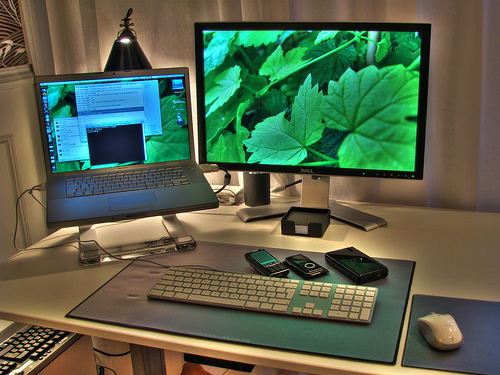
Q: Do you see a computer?
A: Yes, there is a computer.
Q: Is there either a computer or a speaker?
A: Yes, there is a computer.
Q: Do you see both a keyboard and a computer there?
A: Yes, there are both a computer and a keyboard.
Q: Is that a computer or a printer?
A: That is a computer.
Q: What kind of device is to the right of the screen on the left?
A: The device is a computer.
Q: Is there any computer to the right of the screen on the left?
A: Yes, there is a computer to the right of the screen.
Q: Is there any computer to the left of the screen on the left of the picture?
A: No, the computer is to the right of the screen.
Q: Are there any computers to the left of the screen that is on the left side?
A: No, the computer is to the right of the screen.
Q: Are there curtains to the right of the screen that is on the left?
A: No, there is a computer to the right of the screen.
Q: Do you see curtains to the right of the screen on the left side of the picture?
A: No, there is a computer to the right of the screen.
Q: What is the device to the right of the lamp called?
A: The device is a computer.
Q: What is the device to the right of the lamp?
A: The device is a computer.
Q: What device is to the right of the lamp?
A: The device is a computer.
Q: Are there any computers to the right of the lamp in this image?
A: Yes, there is a computer to the right of the lamp.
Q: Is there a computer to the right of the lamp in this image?
A: Yes, there is a computer to the right of the lamp.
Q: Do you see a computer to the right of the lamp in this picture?
A: Yes, there is a computer to the right of the lamp.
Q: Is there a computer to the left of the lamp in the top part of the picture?
A: No, the computer is to the right of the lamp.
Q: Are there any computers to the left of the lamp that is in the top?
A: No, the computer is to the right of the lamp.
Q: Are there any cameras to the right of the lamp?
A: No, there is a computer to the right of the lamp.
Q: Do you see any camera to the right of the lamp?
A: No, there is a computer to the right of the lamp.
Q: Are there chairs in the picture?
A: No, there are no chairs.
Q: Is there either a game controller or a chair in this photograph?
A: No, there are no chairs or game controllers.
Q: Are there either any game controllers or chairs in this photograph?
A: No, there are no chairs or game controllers.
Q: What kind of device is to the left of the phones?
A: The device is a screen.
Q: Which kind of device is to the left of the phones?
A: The device is a screen.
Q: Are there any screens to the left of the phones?
A: Yes, there is a screen to the left of the phones.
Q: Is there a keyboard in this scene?
A: Yes, there is a keyboard.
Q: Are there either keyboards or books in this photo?
A: Yes, there is a keyboard.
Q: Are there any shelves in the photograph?
A: No, there are no shelves.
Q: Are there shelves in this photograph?
A: No, there are no shelves.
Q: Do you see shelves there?
A: No, there are no shelves.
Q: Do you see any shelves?
A: No, there are no shelves.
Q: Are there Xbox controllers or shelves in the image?
A: No, there are no shelves or Xbox controllers.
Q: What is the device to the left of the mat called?
A: The device is a keyboard.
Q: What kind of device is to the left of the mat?
A: The device is a keyboard.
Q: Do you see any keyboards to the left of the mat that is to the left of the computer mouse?
A: Yes, there is a keyboard to the left of the mat.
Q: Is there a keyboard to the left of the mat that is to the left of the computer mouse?
A: Yes, there is a keyboard to the left of the mat.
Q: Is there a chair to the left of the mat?
A: No, there is a keyboard to the left of the mat.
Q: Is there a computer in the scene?
A: Yes, there is a computer.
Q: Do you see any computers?
A: Yes, there is a computer.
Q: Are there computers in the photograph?
A: Yes, there is a computer.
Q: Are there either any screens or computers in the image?
A: Yes, there is a computer.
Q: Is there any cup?
A: No, there are no cups.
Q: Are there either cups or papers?
A: No, there are no cups or papers.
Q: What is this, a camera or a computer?
A: This is a computer.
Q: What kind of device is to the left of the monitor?
A: The device is a computer.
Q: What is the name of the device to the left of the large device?
A: The device is a computer.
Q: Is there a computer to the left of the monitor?
A: Yes, there is a computer to the left of the monitor.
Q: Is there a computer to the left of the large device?
A: Yes, there is a computer to the left of the monitor.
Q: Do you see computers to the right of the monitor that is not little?
A: No, the computer is to the left of the monitor.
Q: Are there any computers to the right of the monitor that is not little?
A: No, the computer is to the left of the monitor.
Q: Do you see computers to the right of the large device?
A: No, the computer is to the left of the monitor.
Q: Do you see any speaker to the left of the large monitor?
A: No, there is a computer to the left of the monitor.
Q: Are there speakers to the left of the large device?
A: No, there is a computer to the left of the monitor.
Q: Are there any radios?
A: No, there are no radios.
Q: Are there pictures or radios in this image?
A: No, there are no radios or pictures.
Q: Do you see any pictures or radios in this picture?
A: No, there are no radios or pictures.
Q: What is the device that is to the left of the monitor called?
A: The device is a screen.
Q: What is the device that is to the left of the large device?
A: The device is a screen.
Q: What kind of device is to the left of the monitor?
A: The device is a screen.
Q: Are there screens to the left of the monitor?
A: Yes, there is a screen to the left of the monitor.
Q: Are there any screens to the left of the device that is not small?
A: Yes, there is a screen to the left of the monitor.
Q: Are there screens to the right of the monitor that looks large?
A: No, the screen is to the left of the monitor.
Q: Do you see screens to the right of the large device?
A: No, the screen is to the left of the monitor.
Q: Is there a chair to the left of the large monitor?
A: No, there is a screen to the left of the monitor.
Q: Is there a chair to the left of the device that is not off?
A: No, there is a screen to the left of the monitor.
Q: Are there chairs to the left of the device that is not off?
A: No, there is a screen to the left of the monitor.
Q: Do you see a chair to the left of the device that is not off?
A: No, there is a screen to the left of the monitor.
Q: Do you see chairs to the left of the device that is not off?
A: No, there is a screen to the left of the monitor.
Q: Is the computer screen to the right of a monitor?
A: No, the screen is to the left of a monitor.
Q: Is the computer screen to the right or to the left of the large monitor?
A: The screen is to the left of the monitor.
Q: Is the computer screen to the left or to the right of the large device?
A: The screen is to the left of the monitor.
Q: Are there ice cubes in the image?
A: No, there are no ice cubes.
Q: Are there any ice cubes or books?
A: No, there are no ice cubes or books.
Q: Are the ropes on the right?
A: Yes, the ropes are on the right of the image.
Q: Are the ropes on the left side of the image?
A: No, the ropes are on the right of the image.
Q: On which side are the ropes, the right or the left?
A: The ropes are on the right of the image.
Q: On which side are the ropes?
A: The ropes are on the right of the image.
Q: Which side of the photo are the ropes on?
A: The ropes are on the right of the image.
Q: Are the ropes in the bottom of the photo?
A: Yes, the ropes are in the bottom of the image.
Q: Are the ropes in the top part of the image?
A: No, the ropes are in the bottom of the image.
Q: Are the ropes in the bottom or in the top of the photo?
A: The ropes are in the bottom of the image.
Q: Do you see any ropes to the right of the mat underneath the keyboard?
A: Yes, there are ropes to the right of the mat.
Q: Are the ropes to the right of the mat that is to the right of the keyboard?
A: Yes, the ropes are to the right of the mat.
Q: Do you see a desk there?
A: Yes, there is a desk.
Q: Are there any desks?
A: Yes, there is a desk.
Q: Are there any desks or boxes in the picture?
A: Yes, there is a desk.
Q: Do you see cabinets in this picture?
A: No, there are no cabinets.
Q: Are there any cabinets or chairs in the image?
A: No, there are no cabinets or chairs.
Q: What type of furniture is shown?
A: The furniture is a desk.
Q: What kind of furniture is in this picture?
A: The furniture is a desk.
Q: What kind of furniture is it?
A: The piece of furniture is a desk.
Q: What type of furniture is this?
A: This is a desk.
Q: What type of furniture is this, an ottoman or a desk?
A: This is a desk.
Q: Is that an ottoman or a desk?
A: That is a desk.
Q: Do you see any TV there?
A: No, there are no televisions.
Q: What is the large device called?
A: The device is a monitor.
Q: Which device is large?
A: The device is a monitor.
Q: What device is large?
A: The device is a monitor.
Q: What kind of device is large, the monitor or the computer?
A: The monitor is large.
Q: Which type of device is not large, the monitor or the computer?
A: The computer is not large.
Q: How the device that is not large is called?
A: The device is a computer.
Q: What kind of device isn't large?
A: The device is a computer.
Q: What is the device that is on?
A: The device is a monitor.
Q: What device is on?
A: The device is a monitor.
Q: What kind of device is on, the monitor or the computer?
A: The monitor is on.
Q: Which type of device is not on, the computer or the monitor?
A: The computer is not on.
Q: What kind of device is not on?
A: The device is a computer.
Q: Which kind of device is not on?
A: The device is a computer.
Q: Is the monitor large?
A: Yes, the monitor is large.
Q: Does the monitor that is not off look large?
A: Yes, the monitor is large.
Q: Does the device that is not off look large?
A: Yes, the monitor is large.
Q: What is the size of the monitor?
A: The monitor is large.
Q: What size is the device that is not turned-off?
A: The monitor is large.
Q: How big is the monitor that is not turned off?
A: The monitor is large.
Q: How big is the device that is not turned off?
A: The monitor is large.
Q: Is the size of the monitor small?
A: No, the monitor is large.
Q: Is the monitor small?
A: No, the monitor is large.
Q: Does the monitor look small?
A: No, the monitor is large.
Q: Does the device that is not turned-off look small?
A: No, the monitor is large.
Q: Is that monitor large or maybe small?
A: The monitor is large.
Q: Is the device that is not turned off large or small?
A: The monitor is large.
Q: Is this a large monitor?
A: Yes, this is a large monitor.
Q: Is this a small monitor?
A: No, this is a large monitor.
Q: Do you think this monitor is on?
A: Yes, the monitor is on.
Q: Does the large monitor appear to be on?
A: Yes, the monitor is on.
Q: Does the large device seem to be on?
A: Yes, the monitor is on.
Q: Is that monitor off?
A: No, the monitor is on.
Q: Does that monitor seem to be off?
A: No, the monitor is on.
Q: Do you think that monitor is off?
A: No, the monitor is on.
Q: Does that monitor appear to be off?
A: No, the monitor is on.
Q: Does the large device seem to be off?
A: No, the monitor is on.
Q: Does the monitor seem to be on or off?
A: The monitor is on.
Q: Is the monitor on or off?
A: The monitor is on.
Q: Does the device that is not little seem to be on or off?
A: The monitor is on.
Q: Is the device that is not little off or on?
A: The monitor is on.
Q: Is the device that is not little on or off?
A: The monitor is on.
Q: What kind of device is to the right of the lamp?
A: The device is a monitor.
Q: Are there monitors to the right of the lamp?
A: Yes, there is a monitor to the right of the lamp.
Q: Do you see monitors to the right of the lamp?
A: Yes, there is a monitor to the right of the lamp.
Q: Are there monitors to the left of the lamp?
A: No, the monitor is to the right of the lamp.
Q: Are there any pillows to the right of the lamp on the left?
A: No, there is a monitor to the right of the lamp.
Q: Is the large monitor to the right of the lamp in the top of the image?
A: Yes, the monitor is to the right of the lamp.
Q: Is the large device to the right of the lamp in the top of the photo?
A: Yes, the monitor is to the right of the lamp.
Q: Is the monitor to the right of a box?
A: No, the monitor is to the right of the lamp.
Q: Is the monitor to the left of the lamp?
A: No, the monitor is to the right of the lamp.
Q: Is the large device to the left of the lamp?
A: No, the monitor is to the right of the lamp.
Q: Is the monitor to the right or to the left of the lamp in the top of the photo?
A: The monitor is to the right of the lamp.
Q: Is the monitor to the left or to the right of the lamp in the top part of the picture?
A: The monitor is to the right of the lamp.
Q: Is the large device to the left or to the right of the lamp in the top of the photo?
A: The monitor is to the right of the lamp.